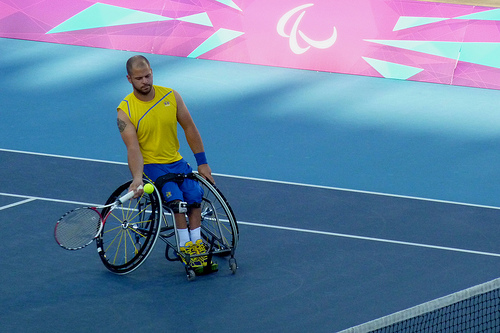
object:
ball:
[141, 182, 157, 196]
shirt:
[111, 86, 188, 167]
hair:
[127, 54, 151, 74]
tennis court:
[4, 144, 497, 332]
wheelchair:
[90, 169, 256, 282]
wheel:
[89, 177, 171, 281]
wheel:
[181, 166, 265, 272]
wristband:
[191, 149, 208, 167]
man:
[116, 55, 216, 268]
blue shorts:
[134, 157, 206, 213]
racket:
[50, 183, 147, 258]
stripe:
[134, 88, 173, 137]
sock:
[190, 224, 203, 246]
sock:
[172, 227, 193, 251]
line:
[3, 146, 499, 214]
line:
[0, 187, 497, 259]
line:
[0, 194, 35, 214]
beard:
[131, 83, 154, 97]